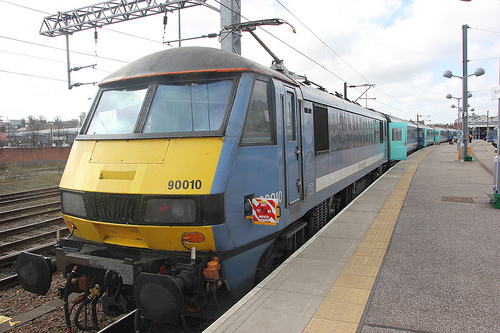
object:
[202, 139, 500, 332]
platform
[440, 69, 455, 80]
light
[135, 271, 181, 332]
bumper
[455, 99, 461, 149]
light post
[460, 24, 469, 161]
gray pole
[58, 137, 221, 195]
yellow section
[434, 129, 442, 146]
doors train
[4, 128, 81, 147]
houses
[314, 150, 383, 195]
stripe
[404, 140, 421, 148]
stripe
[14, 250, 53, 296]
bumper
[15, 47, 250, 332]
front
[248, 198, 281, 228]
sign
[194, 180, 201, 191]
numbers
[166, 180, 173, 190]
black number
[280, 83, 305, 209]
door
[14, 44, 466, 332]
train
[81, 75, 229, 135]
windshield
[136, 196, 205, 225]
lights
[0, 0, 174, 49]
guides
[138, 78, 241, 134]
front windshield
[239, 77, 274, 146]
window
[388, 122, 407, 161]
door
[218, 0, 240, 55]
pole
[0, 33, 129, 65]
power line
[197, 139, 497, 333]
train station